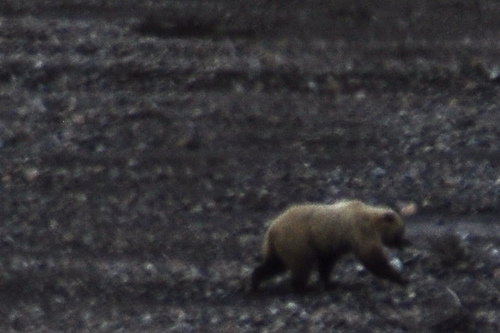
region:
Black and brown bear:
[232, 188, 452, 308]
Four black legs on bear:
[244, 240, 449, 307]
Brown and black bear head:
[365, 197, 430, 260]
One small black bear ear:
[373, 202, 408, 227]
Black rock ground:
[1, 0, 496, 331]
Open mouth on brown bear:
[389, 225, 424, 261]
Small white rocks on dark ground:
[2, 3, 497, 332]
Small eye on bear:
[390, 225, 410, 237]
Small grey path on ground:
[344, 183, 499, 263]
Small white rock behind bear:
[380, 247, 406, 282]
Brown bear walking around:
[225, 186, 424, 325]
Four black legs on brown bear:
[239, 252, 421, 320]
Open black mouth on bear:
[389, 221, 415, 260]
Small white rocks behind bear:
[347, 249, 414, 285]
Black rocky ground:
[4, 4, 497, 327]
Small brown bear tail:
[253, 220, 290, 252]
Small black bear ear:
[376, 208, 407, 222]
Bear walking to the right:
[237, 190, 472, 325]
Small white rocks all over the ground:
[14, 9, 499, 331]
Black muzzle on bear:
[387, 222, 422, 252]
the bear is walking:
[215, 168, 443, 308]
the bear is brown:
[212, 150, 417, 330]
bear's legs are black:
[251, 245, 417, 296]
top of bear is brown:
[242, 184, 412, 265]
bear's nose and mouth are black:
[378, 228, 413, 255]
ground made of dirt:
[2, 1, 498, 330]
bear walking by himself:
[236, 182, 416, 309]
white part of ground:
[132, 252, 162, 280]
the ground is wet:
[6, 14, 489, 327]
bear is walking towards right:
[227, 193, 454, 306]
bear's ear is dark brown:
[375, 204, 398, 229]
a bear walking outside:
[234, 183, 499, 318]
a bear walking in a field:
[159, 141, 491, 312]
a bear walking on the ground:
[199, 162, 474, 329]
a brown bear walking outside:
[232, 176, 475, 315]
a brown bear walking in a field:
[239, 148, 429, 324]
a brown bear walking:
[249, 184, 418, 321]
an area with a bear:
[194, 168, 448, 330]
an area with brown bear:
[205, 186, 495, 302]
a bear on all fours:
[210, 159, 400, 321]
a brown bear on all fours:
[232, 176, 465, 318]